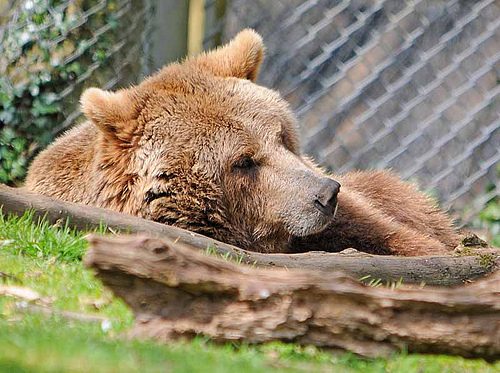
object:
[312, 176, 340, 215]
nose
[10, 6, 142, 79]
wall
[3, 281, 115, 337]
sand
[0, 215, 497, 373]
ground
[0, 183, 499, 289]
branch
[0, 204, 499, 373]
grass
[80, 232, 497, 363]
log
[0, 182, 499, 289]
log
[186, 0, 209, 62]
pole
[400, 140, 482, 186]
mesh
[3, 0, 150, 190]
bush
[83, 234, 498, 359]
wood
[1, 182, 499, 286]
wood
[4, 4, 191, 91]
fence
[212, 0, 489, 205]
fence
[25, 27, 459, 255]
bear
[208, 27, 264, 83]
ears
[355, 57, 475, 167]
part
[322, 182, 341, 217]
part